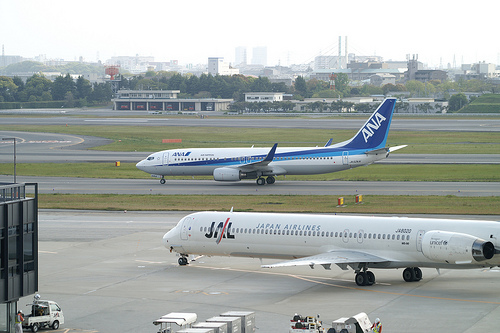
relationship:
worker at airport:
[368, 317, 383, 330] [1, 92, 495, 327]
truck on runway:
[20, 293, 65, 330] [33, 207, 497, 332]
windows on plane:
[198, 224, 412, 242] [160, 209, 499, 286]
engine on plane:
[420, 228, 495, 265] [160, 209, 499, 286]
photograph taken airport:
[3, 10, 484, 326] [1, 92, 495, 327]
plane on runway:
[135, 99, 409, 188] [6, 107, 484, 327]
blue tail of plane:
[340, 97, 408, 171] [135, 99, 409, 188]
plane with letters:
[135, 99, 409, 188] [355, 108, 390, 146]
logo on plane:
[203, 213, 236, 240] [149, 200, 494, 277]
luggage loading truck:
[1, 175, 61, 323] [16, 299, 76, 329]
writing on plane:
[203, 217, 237, 243] [141, 186, 499, 286]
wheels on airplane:
[340, 262, 460, 306] [167, 201, 483, 284]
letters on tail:
[356, 109, 390, 143] [346, 89, 411, 171]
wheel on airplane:
[249, 171, 286, 189] [160, 205, 499, 286]